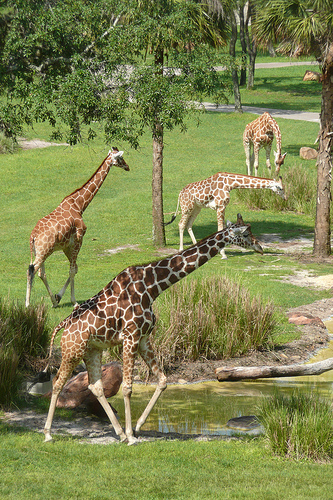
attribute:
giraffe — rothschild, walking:
[23, 147, 131, 305]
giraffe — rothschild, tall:
[241, 110, 286, 176]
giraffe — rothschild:
[161, 172, 290, 252]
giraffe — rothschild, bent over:
[43, 214, 261, 446]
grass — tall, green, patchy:
[234, 162, 315, 218]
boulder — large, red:
[50, 362, 125, 415]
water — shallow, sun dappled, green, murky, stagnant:
[93, 376, 332, 434]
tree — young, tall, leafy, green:
[4, 2, 246, 247]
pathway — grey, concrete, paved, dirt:
[126, 90, 333, 124]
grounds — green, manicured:
[0, 42, 332, 490]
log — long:
[213, 358, 333, 383]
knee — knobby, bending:
[119, 384, 133, 401]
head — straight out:
[230, 210, 266, 256]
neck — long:
[144, 227, 228, 300]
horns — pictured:
[231, 214, 249, 234]